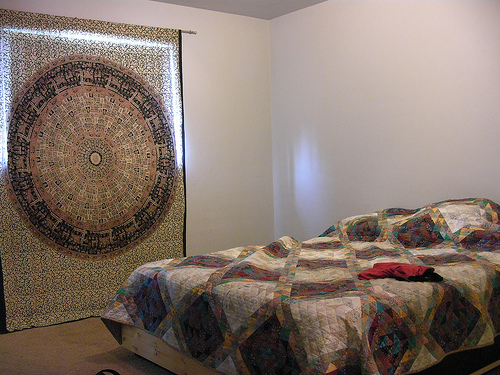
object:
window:
[0, 24, 188, 184]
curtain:
[0, 6, 185, 333]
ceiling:
[153, 0, 330, 22]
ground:
[397, 176, 417, 204]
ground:
[395, 162, 408, 177]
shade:
[1, 27, 179, 315]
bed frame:
[117, 326, 224, 375]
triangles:
[183, 292, 217, 318]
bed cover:
[100, 198, 499, 375]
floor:
[4, 320, 115, 373]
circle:
[3, 55, 178, 259]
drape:
[1, 7, 186, 332]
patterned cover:
[99, 198, 499, 375]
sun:
[0, 21, 181, 167]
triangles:
[404, 344, 443, 374]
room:
[0, 1, 499, 375]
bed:
[98, 199, 500, 375]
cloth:
[358, 261, 445, 283]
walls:
[188, 52, 243, 116]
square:
[413, 279, 486, 361]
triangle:
[436, 283, 448, 302]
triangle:
[383, 307, 394, 319]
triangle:
[434, 340, 446, 358]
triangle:
[419, 344, 431, 355]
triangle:
[423, 301, 440, 323]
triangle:
[210, 301, 224, 324]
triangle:
[216, 291, 269, 333]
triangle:
[172, 299, 189, 315]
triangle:
[228, 318, 244, 333]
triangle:
[183, 342, 192, 351]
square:
[166, 280, 240, 372]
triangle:
[123, 299, 148, 324]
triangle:
[141, 272, 162, 293]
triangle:
[162, 287, 169, 294]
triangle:
[167, 318, 173, 327]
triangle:
[158, 321, 164, 330]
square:
[114, 270, 177, 341]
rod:
[182, 30, 199, 36]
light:
[294, 137, 328, 234]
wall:
[270, 0, 472, 177]